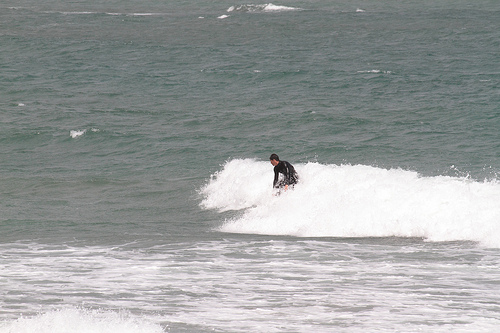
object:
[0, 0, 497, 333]
ocean view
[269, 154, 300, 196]
man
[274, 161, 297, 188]
wetsuit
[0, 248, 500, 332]
splash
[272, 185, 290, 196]
surfboard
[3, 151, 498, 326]
sea foam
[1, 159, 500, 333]
wave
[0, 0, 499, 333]
water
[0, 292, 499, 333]
shore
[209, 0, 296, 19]
wave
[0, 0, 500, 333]
background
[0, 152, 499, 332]
suds